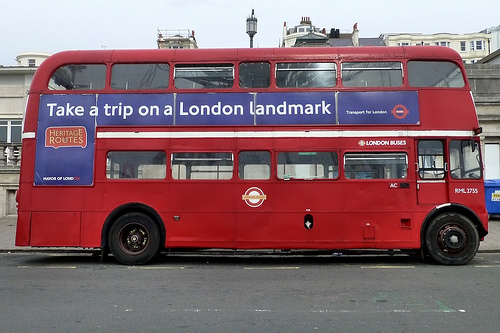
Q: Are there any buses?
A: Yes, there is a bus.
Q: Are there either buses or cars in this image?
A: Yes, there is a bus.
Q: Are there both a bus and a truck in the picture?
A: No, there is a bus but no trucks.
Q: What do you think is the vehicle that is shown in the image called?
A: The vehicle is a bus.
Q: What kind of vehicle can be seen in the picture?
A: The vehicle is a bus.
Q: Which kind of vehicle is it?
A: The vehicle is a bus.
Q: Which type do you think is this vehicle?
A: That is a bus.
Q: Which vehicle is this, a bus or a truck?
A: That is a bus.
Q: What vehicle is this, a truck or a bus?
A: That is a bus.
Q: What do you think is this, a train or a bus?
A: This is a bus.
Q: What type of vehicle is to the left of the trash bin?
A: The vehicle is a bus.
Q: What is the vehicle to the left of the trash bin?
A: The vehicle is a bus.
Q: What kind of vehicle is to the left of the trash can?
A: The vehicle is a bus.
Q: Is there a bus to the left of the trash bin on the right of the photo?
A: Yes, there is a bus to the left of the trash can.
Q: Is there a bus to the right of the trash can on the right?
A: No, the bus is to the left of the trash bin.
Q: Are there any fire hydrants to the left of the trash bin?
A: No, there is a bus to the left of the trash bin.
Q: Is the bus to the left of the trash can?
A: Yes, the bus is to the left of the trash can.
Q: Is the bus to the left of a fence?
A: No, the bus is to the left of the trash can.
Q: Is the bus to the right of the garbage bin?
A: No, the bus is to the left of the garbage bin.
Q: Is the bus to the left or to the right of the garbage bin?
A: The bus is to the left of the garbage bin.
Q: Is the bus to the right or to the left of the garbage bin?
A: The bus is to the left of the garbage bin.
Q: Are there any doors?
A: Yes, there is a door.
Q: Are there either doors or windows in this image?
A: Yes, there is a door.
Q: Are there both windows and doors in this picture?
A: Yes, there are both a door and a window.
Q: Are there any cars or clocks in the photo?
A: No, there are no cars or clocks.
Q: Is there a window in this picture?
A: Yes, there is a window.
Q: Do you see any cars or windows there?
A: Yes, there is a window.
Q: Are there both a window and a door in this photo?
A: Yes, there are both a window and a door.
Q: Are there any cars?
A: No, there are no cars.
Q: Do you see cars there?
A: No, there are no cars.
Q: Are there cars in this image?
A: No, there are no cars.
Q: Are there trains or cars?
A: No, there are no cars or trains.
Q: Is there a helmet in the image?
A: No, there are no helmets.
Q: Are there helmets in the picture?
A: No, there are no helmets.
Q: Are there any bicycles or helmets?
A: No, there are no helmets or bicycles.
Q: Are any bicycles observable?
A: No, there are no bicycles.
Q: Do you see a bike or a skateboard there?
A: No, there are no bikes or skateboards.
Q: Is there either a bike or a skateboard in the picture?
A: No, there are no bikes or skateboards.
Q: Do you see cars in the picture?
A: No, there are no cars.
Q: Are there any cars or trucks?
A: No, there are no cars or trucks.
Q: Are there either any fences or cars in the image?
A: No, there are no cars or fences.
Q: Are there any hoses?
A: No, there are no hoses.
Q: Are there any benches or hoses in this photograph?
A: No, there are no hoses or benches.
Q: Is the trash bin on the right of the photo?
A: Yes, the trash bin is on the right of the image.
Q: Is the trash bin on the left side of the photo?
A: No, the trash bin is on the right of the image.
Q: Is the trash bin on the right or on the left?
A: The trash bin is on the right of the image.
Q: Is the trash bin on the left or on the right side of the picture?
A: The trash bin is on the right of the image.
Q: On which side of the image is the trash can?
A: The trash can is on the right of the image.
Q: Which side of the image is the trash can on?
A: The trash can is on the right of the image.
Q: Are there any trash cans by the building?
A: Yes, there is a trash can by the building.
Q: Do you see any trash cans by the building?
A: Yes, there is a trash can by the building.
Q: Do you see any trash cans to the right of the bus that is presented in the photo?
A: Yes, there is a trash can to the right of the bus.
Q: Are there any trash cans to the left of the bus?
A: No, the trash can is to the right of the bus.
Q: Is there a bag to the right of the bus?
A: No, there is a trash can to the right of the bus.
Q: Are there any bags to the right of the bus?
A: No, there is a trash can to the right of the bus.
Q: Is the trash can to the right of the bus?
A: Yes, the trash can is to the right of the bus.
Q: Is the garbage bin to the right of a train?
A: No, the garbage bin is to the right of the bus.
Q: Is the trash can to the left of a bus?
A: No, the trash can is to the right of a bus.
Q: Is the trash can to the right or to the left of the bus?
A: The trash can is to the right of the bus.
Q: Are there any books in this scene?
A: No, there are no books.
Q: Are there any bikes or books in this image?
A: No, there are no books or bikes.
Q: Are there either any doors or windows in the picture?
A: Yes, there is a window.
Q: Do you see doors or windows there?
A: Yes, there is a window.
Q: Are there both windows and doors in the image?
A: Yes, there are both a window and a door.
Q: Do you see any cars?
A: No, there are no cars.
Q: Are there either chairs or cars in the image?
A: No, there are no cars or chairs.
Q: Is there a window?
A: Yes, there is a window.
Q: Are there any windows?
A: Yes, there is a window.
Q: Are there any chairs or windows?
A: Yes, there is a window.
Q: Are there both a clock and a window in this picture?
A: No, there is a window but no clocks.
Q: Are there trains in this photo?
A: No, there are no trains.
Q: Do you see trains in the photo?
A: No, there are no trains.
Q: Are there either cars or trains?
A: No, there are no trains or cars.